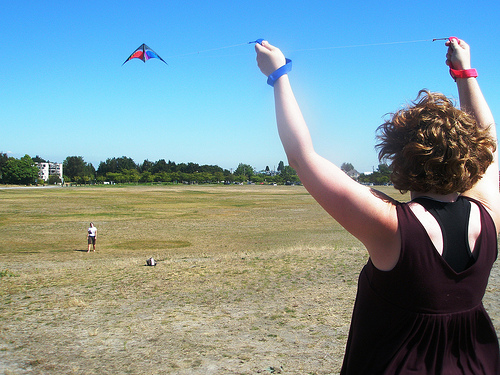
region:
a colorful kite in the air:
[122, 40, 169, 62]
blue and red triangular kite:
[120, 40, 170, 68]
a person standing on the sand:
[81, 225, 101, 253]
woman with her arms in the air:
[250, 36, 495, 373]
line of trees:
[67, 154, 274, 186]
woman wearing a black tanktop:
[324, 89, 489, 374]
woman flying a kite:
[124, 11, 498, 188]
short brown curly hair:
[376, 83, 493, 198]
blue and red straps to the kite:
[243, 31, 484, 83]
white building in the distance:
[29, 154, 66, 188]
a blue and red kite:
[121, 39, 176, 69]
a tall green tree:
[60, 150, 88, 180]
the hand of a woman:
[254, 38, 288, 78]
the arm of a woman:
[268, 80, 391, 243]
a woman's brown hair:
[374, 87, 498, 195]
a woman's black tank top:
[338, 193, 498, 373]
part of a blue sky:
[3, 4, 110, 154]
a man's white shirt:
[87, 227, 101, 236]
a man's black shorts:
[88, 235, 101, 243]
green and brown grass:
[6, 183, 210, 222]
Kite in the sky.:
[98, 34, 173, 79]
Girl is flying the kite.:
[248, 32, 498, 374]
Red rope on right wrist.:
[430, 30, 485, 96]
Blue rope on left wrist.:
[240, 30, 300, 95]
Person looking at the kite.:
[74, 210, 110, 261]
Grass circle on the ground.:
[108, 228, 195, 253]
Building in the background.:
[28, 155, 75, 184]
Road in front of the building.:
[1, 170, 76, 198]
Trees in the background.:
[62, 148, 407, 188]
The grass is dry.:
[11, 277, 325, 372]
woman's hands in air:
[223, 6, 499, 257]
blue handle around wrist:
[241, 16, 334, 106]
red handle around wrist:
[428, 53, 499, 100]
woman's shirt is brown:
[335, 174, 496, 371]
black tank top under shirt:
[415, 183, 487, 280]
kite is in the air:
[103, 8, 208, 92]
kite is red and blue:
[111, 15, 182, 95]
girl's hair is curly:
[364, 76, 486, 228]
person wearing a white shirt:
[69, 210, 109, 242]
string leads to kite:
[281, 14, 450, 48]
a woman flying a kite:
[120, 28, 497, 371]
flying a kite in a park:
[76, 22, 498, 329]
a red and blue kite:
[113, 32, 170, 82]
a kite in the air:
[100, 10, 189, 92]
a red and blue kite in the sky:
[95, 13, 215, 118]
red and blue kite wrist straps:
[231, 30, 490, 93]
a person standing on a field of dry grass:
[0, 203, 317, 362]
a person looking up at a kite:
[49, 200, 123, 267]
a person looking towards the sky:
[62, 189, 129, 277]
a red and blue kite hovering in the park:
[79, 10, 186, 125]